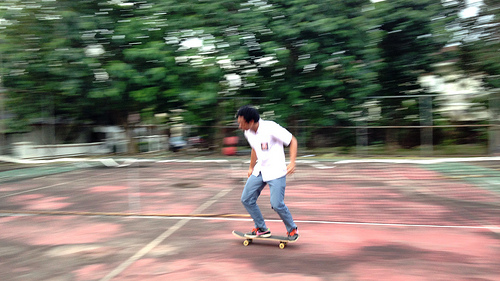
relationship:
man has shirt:
[231, 108, 298, 239] [243, 117, 291, 184]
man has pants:
[231, 108, 298, 239] [241, 170, 297, 233]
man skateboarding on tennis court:
[231, 108, 298, 239] [1, 155, 500, 278]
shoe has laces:
[245, 226, 274, 240] [250, 227, 260, 234]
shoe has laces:
[286, 227, 300, 239] [289, 228, 296, 236]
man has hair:
[231, 108, 298, 239] [236, 105, 261, 125]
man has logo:
[231, 108, 298, 239] [261, 142, 270, 150]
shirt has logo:
[243, 117, 291, 184] [261, 142, 270, 150]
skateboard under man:
[233, 227, 299, 247] [231, 108, 298, 239]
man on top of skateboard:
[231, 108, 298, 239] [233, 227, 299, 247]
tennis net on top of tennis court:
[2, 154, 500, 229] [1, 155, 500, 278]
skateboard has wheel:
[233, 227, 299, 247] [242, 240, 251, 247]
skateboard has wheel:
[233, 227, 299, 247] [278, 241, 285, 249]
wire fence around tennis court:
[2, 85, 499, 161] [1, 155, 500, 278]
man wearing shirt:
[231, 108, 298, 239] [243, 117, 291, 184]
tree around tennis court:
[2, 2, 222, 137] [1, 155, 500, 278]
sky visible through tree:
[0, 1, 499, 123] [2, 2, 222, 137]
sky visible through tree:
[0, 1, 499, 123] [220, 1, 499, 138]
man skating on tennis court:
[231, 108, 298, 239] [1, 155, 500, 278]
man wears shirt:
[231, 108, 298, 239] [243, 117, 291, 184]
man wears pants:
[231, 108, 298, 239] [241, 170, 297, 233]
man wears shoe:
[231, 108, 298, 239] [245, 226, 274, 240]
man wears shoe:
[231, 108, 298, 239] [286, 227, 300, 239]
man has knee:
[231, 108, 298, 239] [241, 197, 255, 208]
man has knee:
[231, 108, 298, 239] [271, 203, 286, 211]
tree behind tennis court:
[2, 2, 222, 137] [1, 155, 500, 278]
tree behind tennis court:
[220, 1, 499, 138] [1, 155, 500, 278]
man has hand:
[231, 108, 298, 239] [246, 169, 256, 179]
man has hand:
[231, 108, 298, 239] [286, 159, 298, 177]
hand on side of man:
[246, 169, 256, 179] [231, 108, 298, 239]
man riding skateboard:
[231, 108, 298, 239] [233, 227, 299, 247]